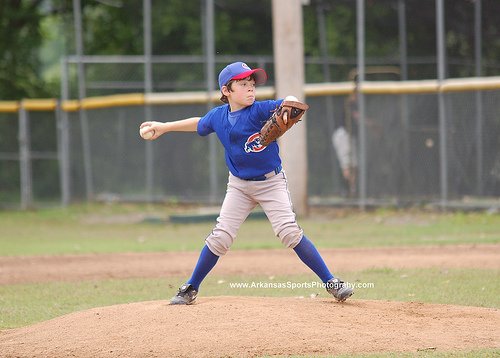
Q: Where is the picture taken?
A: A field.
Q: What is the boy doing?
A: Pitching.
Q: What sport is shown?
A: Baseball.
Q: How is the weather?
A: Clear.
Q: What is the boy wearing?
A: A uniform.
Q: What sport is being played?
A: Baseball.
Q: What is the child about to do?
A: Throw a baseball.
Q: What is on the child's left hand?
A: A catcher's mitt.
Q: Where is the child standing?
A: On a mound of dirt.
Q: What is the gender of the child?
A: Male.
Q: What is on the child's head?
A: A hat.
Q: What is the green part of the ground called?
A: Grass.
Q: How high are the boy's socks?
A: Knee high.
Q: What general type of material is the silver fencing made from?
A: Metal.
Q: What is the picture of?
A: A boy throwing a ball.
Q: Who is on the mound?
A: The pitcher.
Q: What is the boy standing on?
A: A mound of dirt.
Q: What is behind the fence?
A: Trees.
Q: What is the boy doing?
A: Playing baseball.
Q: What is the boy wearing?
A: Blue socks.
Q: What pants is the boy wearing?
A: Beige baseball pants.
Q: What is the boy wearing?
A: A baseball uniform.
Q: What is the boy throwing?
A: A baseball.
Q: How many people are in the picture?
A: 1.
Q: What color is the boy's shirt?
A: Blue.